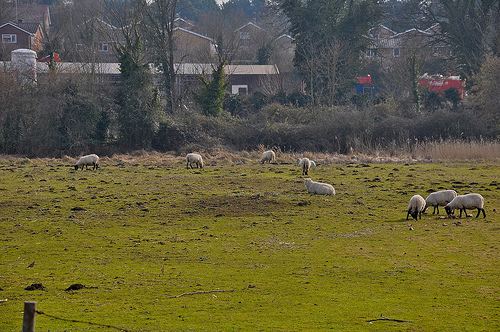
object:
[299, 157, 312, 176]
sheep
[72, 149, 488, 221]
flock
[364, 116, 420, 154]
bushes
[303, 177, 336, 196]
sheep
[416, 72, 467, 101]
house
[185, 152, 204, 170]
grazing sheep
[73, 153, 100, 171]
sheep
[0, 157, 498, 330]
grass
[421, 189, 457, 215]
sheep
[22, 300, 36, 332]
post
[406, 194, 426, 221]
sheep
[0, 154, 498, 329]
field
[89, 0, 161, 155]
tree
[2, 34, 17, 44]
window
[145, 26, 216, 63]
house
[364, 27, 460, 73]
house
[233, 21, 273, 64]
house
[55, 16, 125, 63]
house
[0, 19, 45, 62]
house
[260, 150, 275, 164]
sheep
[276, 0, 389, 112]
trees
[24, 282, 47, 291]
rocks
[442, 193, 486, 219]
sheep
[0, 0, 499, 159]
background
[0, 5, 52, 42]
building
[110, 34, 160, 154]
vine